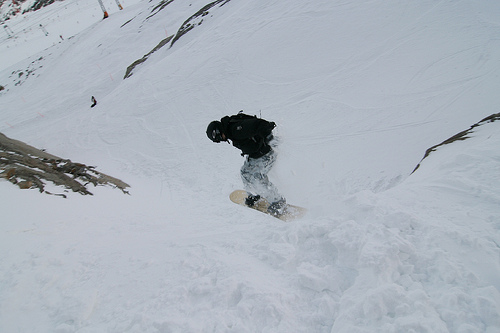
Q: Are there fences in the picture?
A: No, there are no fences.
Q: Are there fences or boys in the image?
A: No, there are no fences or boys.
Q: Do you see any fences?
A: No, there are no fences.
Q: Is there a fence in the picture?
A: No, there are no fences.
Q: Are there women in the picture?
A: No, there are no women.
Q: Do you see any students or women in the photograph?
A: No, there are no women or students.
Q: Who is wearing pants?
A: The man is wearing pants.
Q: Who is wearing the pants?
A: The man is wearing pants.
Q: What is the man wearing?
A: The man is wearing trousers.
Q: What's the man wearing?
A: The man is wearing trousers.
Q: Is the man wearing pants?
A: Yes, the man is wearing pants.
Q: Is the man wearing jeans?
A: No, the man is wearing pants.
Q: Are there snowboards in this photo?
A: Yes, there is a snowboard.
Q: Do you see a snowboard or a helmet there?
A: Yes, there is a snowboard.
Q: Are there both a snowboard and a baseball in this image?
A: No, there is a snowboard but no baseballs.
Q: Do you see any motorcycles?
A: No, there are no motorcycles.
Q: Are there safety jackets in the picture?
A: No, there are no safety jackets.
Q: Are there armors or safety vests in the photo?
A: No, there are no safety vests or armors.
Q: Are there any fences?
A: No, there are no fences.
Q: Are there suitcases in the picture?
A: No, there are no suitcases.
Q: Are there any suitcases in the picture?
A: No, there are no suitcases.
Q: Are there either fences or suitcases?
A: No, there are no suitcases or fences.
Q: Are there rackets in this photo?
A: No, there are no rackets.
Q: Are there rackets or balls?
A: No, there are no rackets or balls.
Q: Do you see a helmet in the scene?
A: Yes, there is a helmet.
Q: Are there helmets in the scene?
A: Yes, there is a helmet.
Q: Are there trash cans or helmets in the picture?
A: Yes, there is a helmet.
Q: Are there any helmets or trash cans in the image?
A: Yes, there is a helmet.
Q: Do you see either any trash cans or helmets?
A: Yes, there is a helmet.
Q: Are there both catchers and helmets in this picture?
A: No, there is a helmet but no catchers.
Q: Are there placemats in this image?
A: No, there are no placemats.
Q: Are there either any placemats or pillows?
A: No, there are no placemats or pillows.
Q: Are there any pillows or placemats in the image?
A: No, there are no placemats or pillows.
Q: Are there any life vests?
A: No, there are no life vests.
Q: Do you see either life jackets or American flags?
A: No, there are no life jackets or American flags.